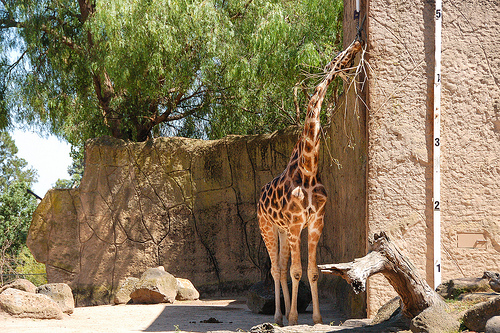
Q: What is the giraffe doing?
A: Giraffe is eating branches over head.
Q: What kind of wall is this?
A: Large beige rock wall.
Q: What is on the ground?
A: Tree stump.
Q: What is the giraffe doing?
A: Eating.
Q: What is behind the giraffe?
A: Wall.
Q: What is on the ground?
A: Log.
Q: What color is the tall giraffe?
A: Brown and white.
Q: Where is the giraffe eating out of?
A: Tall window.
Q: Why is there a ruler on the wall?
A: To calculate height.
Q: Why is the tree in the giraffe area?
A: The tree is in the giraffe area so that the giraffe can eat the leaves.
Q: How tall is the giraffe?
A: The giraffe is about 5 meters tall.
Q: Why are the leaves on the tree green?
A: The leaves are green because they have green Chloroplasts.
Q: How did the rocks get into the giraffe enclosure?
A: Humans placed the rocks in the giraffes' enclosure.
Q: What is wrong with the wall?
A: Full of cracks.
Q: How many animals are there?
A: 1.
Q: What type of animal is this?
A: Giraffe.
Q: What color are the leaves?
A: Green.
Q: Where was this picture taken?
A: Zoo.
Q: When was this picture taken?
A: Daytime.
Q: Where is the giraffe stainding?
A: Next to building.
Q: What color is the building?
A: Tan.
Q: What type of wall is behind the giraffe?
A: Stone wall.